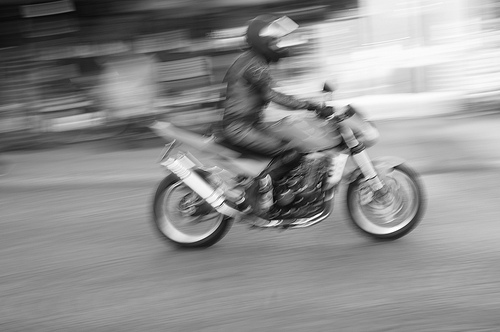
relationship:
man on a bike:
[221, 13, 334, 208] [153, 15, 425, 249]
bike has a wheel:
[153, 15, 425, 249] [154, 170, 232, 248]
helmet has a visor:
[247, 16, 307, 64] [261, 14, 299, 41]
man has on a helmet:
[221, 13, 334, 208] [247, 16, 307, 64]